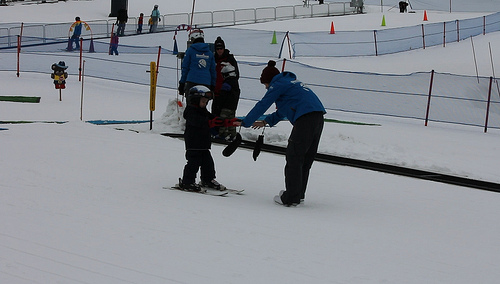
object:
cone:
[381, 15, 387, 26]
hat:
[260, 60, 281, 84]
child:
[179, 85, 241, 193]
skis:
[163, 186, 228, 196]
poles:
[478, 77, 493, 133]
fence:
[420, 69, 491, 133]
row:
[423, 70, 499, 133]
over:
[241, 72, 328, 128]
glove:
[222, 132, 242, 157]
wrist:
[233, 119, 249, 129]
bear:
[51, 61, 70, 90]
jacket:
[179, 42, 216, 86]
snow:
[415, 120, 497, 151]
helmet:
[187, 85, 214, 108]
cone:
[423, 10, 429, 21]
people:
[150, 5, 161, 33]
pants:
[181, 147, 216, 185]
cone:
[270, 30, 278, 44]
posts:
[78, 38, 83, 82]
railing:
[317, 153, 500, 193]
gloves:
[208, 117, 225, 128]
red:
[223, 122, 227, 125]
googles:
[201, 91, 214, 98]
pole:
[424, 70, 435, 126]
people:
[233, 60, 328, 207]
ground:
[6, 160, 497, 283]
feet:
[179, 181, 201, 191]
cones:
[329, 21, 337, 34]